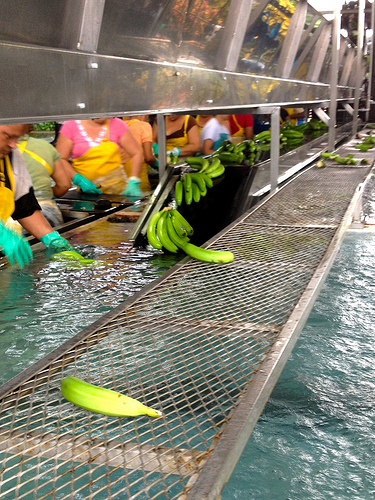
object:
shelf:
[1, 127, 373, 499]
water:
[0, 167, 373, 498]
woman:
[199, 113, 229, 155]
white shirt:
[200, 118, 230, 147]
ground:
[300, 146, 308, 152]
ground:
[272, 145, 290, 183]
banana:
[171, 206, 193, 233]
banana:
[170, 213, 186, 238]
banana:
[155, 216, 175, 252]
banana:
[146, 207, 164, 249]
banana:
[165, 214, 185, 246]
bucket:
[143, 158, 258, 237]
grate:
[154, 287, 238, 384]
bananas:
[169, 164, 211, 207]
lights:
[286, 1, 372, 53]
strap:
[15, 140, 56, 174]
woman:
[15, 120, 72, 232]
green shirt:
[15, 134, 60, 197]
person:
[53, 118, 144, 199]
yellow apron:
[72, 128, 127, 193]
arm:
[8, 171, 101, 275]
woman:
[0, 121, 71, 269]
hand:
[43, 221, 81, 263]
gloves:
[41, 230, 87, 272]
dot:
[75, 119, 82, 124]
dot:
[78, 123, 84, 128]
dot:
[81, 131, 87, 135]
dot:
[85, 137, 93, 141]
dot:
[100, 130, 106, 135]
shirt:
[59, 117, 128, 155]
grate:
[0, 136, 373, 499]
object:
[125, 378, 334, 438]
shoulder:
[21, 138, 55, 170]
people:
[2, 114, 60, 267]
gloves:
[2, 227, 36, 269]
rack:
[0, 216, 365, 495]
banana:
[51, 371, 165, 427]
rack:
[4, 405, 88, 482]